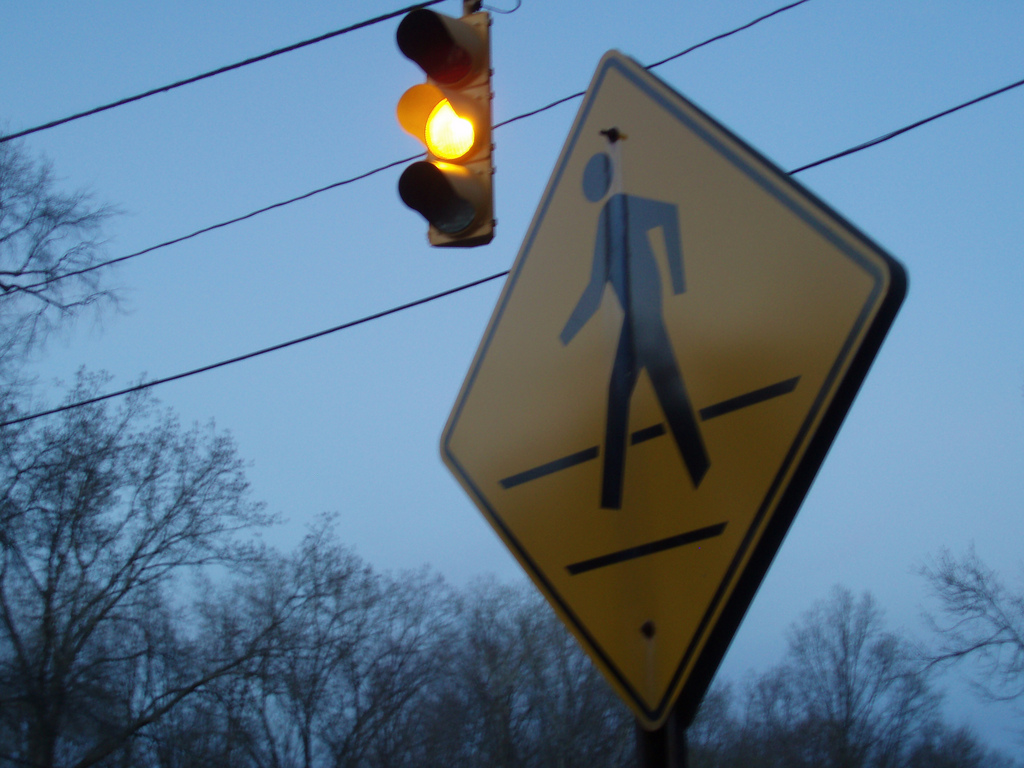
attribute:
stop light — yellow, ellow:
[393, 1, 495, 248]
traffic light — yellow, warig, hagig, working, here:
[396, 84, 485, 160]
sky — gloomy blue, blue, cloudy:
[1, 0, 1021, 768]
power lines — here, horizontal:
[1, 0, 1023, 432]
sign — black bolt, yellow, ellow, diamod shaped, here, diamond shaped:
[438, 46, 907, 729]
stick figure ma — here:
[559, 154, 716, 503]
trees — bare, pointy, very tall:
[4, 140, 1021, 767]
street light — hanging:
[395, 2, 499, 257]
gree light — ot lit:
[398, 160, 483, 240]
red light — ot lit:
[396, 8, 479, 88]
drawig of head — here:
[578, 153, 617, 207]